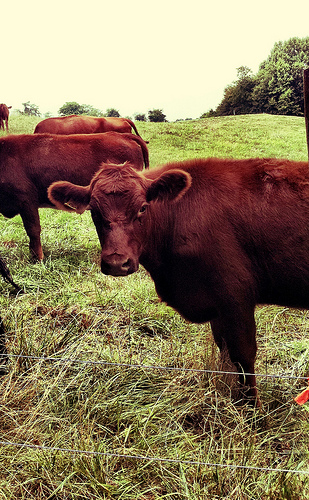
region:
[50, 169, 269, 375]
the cow is brown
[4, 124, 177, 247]
the cow is brown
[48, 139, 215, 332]
the cow is looking at the camera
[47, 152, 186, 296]
a brown cow with big ears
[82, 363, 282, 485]
a barbed wire fence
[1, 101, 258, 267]
four cows near a fence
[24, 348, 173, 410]
tall grass in a field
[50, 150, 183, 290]
a cow with a tag attached to its ear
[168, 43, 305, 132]
green trees up on a hill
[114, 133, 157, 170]
a cows tail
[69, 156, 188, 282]
a cow with its head turned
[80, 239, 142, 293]
a cow's brown nose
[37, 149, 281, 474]
a cow standing next to a fence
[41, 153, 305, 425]
brown cow facing camera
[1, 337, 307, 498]
silver barbed wire fence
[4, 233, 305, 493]
tall grass in foreground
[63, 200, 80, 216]
tag in cow's right ear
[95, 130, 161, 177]
back end of a left facing cow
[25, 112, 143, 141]
distant cow with head down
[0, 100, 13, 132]
distant cow facing camera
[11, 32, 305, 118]
grove of trees in background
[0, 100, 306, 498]
green grassy cow pasture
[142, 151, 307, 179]
thick brown back fur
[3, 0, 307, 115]
light in daytime sky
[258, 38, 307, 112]
green leaves on tree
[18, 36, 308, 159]
line of trees on hill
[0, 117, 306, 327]
green grass of pasture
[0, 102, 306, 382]
four brown standing cows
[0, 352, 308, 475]
metal wires of fence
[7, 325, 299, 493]
legs in tall grass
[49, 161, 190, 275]
cow looking at camera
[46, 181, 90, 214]
cow ear with tag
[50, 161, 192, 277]
two ears on head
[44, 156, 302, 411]
This is a cow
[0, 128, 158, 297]
This is a cow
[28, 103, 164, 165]
This is a cow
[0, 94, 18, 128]
This is a cow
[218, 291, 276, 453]
This is a leg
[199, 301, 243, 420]
This is a leg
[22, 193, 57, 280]
This is a leg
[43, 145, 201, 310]
Head of a cow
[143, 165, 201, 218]
Ear of a cow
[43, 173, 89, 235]
Ear of a cow